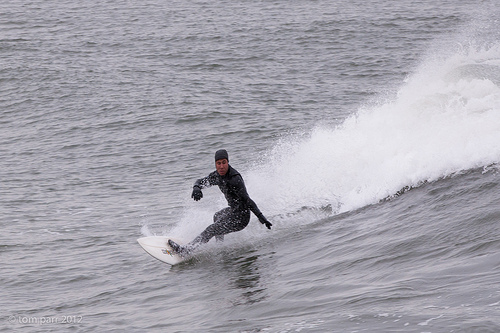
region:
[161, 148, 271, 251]
surfer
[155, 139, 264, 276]
surfer in ocean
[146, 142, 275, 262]
male surfer in ocean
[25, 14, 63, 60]
waves in white and gray ocean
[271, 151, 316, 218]
waves in white and gray ocean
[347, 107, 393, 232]
waves in white and gray ocean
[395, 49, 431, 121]
waves in white and gray ocean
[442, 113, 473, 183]
waves in white and gray ocean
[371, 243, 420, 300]
waves in white and gray ocean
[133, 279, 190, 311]
waves in white and gray ocean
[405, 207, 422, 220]
part of the sky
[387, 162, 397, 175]
part of an ocean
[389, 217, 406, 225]
part of the sea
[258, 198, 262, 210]
part of an arm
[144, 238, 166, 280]
part of a board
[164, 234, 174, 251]
edge of a board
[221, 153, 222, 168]
head of a man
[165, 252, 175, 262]
tip of a board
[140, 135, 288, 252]
male surfer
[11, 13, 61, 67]
white and gray ocean waves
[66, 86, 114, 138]
white and gray ocean waves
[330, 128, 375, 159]
white and gray ocean waves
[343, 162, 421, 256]
white and gray ocean waves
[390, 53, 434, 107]
white and gray ocean waves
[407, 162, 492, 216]
white and gray ocean waves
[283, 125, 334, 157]
white and gray ocean waves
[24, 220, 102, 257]
white and gray ocean waves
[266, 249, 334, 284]
white and gray ocean waves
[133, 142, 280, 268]
A surfer riding a wave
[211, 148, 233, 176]
the surfer's head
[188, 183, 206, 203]
the surfer's left hand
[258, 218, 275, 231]
the surfer's right hand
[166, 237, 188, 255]
the surfer's left foot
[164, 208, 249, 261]
the surfer's left leg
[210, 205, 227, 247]
the surfer's right leg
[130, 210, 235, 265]
the surfer's board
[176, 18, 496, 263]
water being sprayed in the wake of his surf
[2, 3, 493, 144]
water behind the surfer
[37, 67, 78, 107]
white and gray ocean waves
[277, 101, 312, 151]
white and gray ocean waves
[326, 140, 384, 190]
white and gray ocean waves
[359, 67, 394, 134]
white and gray ocean waves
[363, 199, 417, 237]
white and gray ocean waves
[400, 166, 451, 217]
white and gray ocean waves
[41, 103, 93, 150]
white and gray ocean waves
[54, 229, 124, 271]
white and gray ocean waves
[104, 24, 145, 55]
white and gray ocean waves